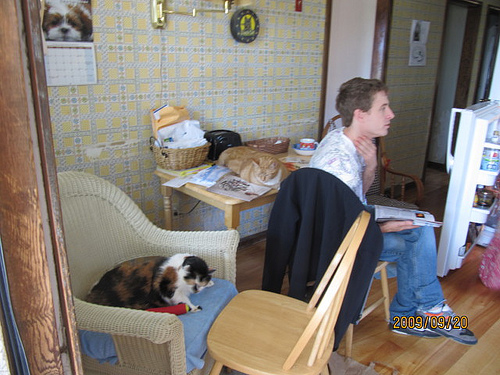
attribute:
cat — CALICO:
[77, 252, 216, 316]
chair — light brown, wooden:
[268, 268, 342, 359]